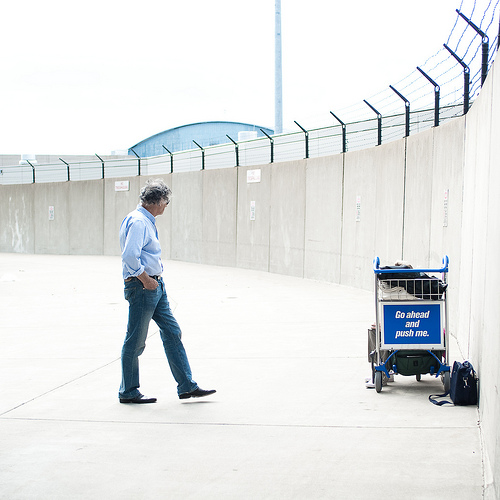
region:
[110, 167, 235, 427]
Man walking along the ground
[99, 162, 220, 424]
Man wearing blue jeans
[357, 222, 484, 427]
A cart with belongings in it parked against the wall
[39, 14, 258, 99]
White, overcast sky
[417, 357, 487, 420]
Man's black bag sitting on the ground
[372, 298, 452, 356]
Sign place on the cart encouraging it's usage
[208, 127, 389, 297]
Large cement wall with wire across the top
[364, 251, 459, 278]
Blue handle of the cart for pushing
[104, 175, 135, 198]
Sign posted on the cement wall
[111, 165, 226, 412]
Man with his hands in his pockets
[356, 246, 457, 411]
cart is metal and blue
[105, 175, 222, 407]
man with hand in pocket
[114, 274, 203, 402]
blue jeans on man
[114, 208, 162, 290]
light blue dress shirt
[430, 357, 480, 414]
black bag on ground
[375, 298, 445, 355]
sign on back of cart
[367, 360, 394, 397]
wheel on back of cart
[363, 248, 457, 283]
blue handle on cart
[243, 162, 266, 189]
sign on cement wall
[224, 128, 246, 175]
bent rods over wall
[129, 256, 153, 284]
rolled up shirt sleeve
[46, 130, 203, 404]
Person walking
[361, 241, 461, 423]
A cart to hull things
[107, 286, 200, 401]
A man with bluejeans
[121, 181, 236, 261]
A man with grey hair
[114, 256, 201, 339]
Man with hands in his pockets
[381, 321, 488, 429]
A case next to the cart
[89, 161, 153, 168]
Barb wire on top of the wall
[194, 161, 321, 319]
Cement walls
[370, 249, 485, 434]
A blue handle on the cart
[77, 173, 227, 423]
A man walking along the wall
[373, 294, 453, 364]
push me sign on back of cart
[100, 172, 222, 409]
man in blue jeans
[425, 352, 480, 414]
blue brief case on ground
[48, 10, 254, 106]
overcast sky with no sun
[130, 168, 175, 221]
balding grey head of hair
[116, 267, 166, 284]
brown leather belt with gold buckle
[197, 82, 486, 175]
barb wire fence on top of concrete walls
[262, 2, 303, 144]
tall concrete smoke stack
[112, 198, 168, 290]
light blue button down shirt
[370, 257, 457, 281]
blue handle of cart